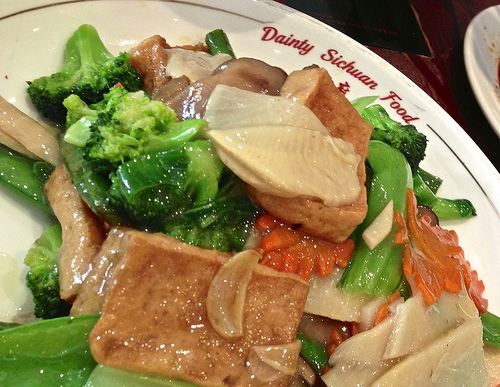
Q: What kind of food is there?
A: Asian.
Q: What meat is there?
A: Beef.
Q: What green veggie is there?
A: Broccoli.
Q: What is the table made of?
A: Wood.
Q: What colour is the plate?
A: White.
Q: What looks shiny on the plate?
A: The food.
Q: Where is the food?
A: On white plate.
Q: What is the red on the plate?
A: Words.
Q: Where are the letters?
A: On the dish.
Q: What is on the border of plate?
A: Letters.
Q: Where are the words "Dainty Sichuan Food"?
A: On plate.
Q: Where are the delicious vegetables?
A: On plate.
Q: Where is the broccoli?
A: On plate.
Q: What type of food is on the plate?
A: Sichuan food.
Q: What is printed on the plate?
A: Dainty Sichuan Food.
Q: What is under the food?
A: A plate.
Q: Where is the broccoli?
A: On the plate.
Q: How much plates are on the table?
A: Two.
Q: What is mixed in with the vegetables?
A: Tofu.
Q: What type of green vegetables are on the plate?
A: Snap peas and broccoli.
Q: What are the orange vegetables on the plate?
A: Carrots.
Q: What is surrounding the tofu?
A: Vegetables.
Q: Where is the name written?
A: On the plate.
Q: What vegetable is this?
A: Broccoli.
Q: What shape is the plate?
A: Round.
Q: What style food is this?
A: Asian.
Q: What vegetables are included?
A: Broccoli and carrots.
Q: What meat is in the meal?
A: Chicken.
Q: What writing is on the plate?
A: Restaurant name.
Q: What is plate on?
A: Wooden table.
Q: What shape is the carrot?
A: Leaf.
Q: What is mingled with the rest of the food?
A: Pasta.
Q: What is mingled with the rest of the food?
A: Broccoli spear.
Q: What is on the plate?
A: Food.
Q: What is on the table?
A: A plate.